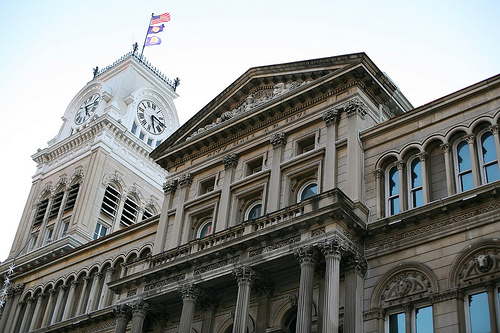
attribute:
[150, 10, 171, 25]
flag — american, flying, waving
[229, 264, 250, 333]
pillar — stone, support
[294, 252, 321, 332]
pillar — stone, support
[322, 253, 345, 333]
pillar — stone, support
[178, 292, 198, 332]
pillar — stone, support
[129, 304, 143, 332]
pillar — stone, support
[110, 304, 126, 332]
pillar — stone, support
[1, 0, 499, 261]
sky — blue, clear, hazy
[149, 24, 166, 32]
flag — blue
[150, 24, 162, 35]
circle — white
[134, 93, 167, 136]
clock — large, white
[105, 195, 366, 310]
balcony — stone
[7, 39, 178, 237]
tower — white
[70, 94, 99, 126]
clock — white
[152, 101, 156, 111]
numeral — roman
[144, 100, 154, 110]
numeral — roman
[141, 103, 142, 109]
numeral — roman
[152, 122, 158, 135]
numeral — roman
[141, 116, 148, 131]
numeral — roman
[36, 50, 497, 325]
building — tan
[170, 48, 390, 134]
facade — Roman style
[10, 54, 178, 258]
building — white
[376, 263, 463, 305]
gargoyle — bull head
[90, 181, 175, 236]
window — white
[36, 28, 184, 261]
building — white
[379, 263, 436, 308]
gargoyles — horse head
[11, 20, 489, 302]
tower — Roman numeral, clock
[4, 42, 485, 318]
building — old, rusty, white, stone, tan